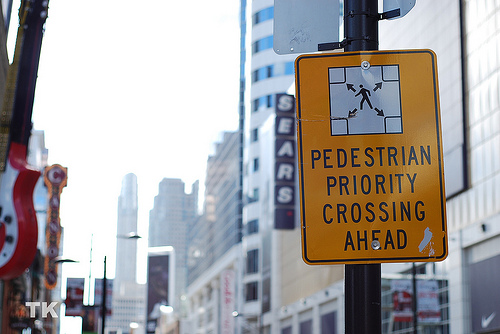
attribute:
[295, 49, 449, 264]
sign — multicolored, yellow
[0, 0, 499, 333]
cityscape — blurry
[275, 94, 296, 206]
sears — blue and white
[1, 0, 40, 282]
guitar — red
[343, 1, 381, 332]
pole — black, tall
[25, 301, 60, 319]
logo — white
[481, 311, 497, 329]
logo — on the marquee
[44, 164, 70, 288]
sign — red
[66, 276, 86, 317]
flag — hanging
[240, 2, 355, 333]
building — tall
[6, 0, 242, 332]
sky — white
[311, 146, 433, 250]
words — black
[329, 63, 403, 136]
square — white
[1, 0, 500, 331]
buildings — tall